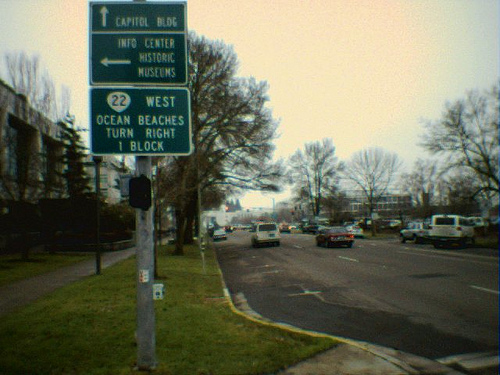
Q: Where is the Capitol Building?
A: Straight ahead.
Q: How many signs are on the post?
A: Three.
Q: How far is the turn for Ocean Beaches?
A: One block.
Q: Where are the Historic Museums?
A: To the left.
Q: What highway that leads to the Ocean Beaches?
A: 22.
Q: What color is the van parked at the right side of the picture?
A: White.